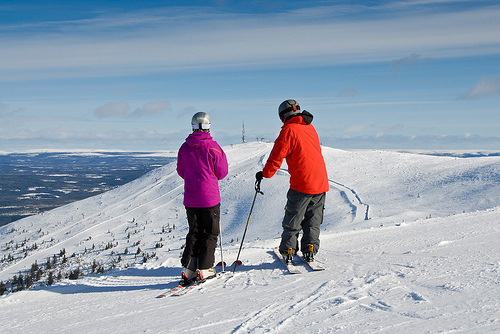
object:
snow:
[7, 316, 46, 334]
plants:
[127, 232, 130, 238]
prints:
[360, 299, 392, 312]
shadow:
[30, 281, 160, 294]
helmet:
[190, 110, 212, 130]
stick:
[232, 174, 262, 274]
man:
[255, 97, 331, 264]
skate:
[269, 243, 324, 274]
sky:
[3, 2, 498, 87]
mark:
[364, 208, 369, 220]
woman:
[172, 110, 232, 284]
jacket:
[259, 117, 329, 195]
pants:
[277, 194, 326, 263]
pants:
[181, 204, 221, 268]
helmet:
[277, 99, 302, 117]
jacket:
[174, 130, 229, 208]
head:
[277, 99, 302, 119]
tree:
[57, 270, 62, 281]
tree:
[44, 256, 51, 271]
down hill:
[5, 193, 168, 256]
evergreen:
[97, 265, 101, 273]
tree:
[89, 236, 92, 241]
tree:
[16, 274, 25, 292]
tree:
[168, 248, 171, 252]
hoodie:
[185, 131, 213, 148]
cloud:
[6, 59, 41, 76]